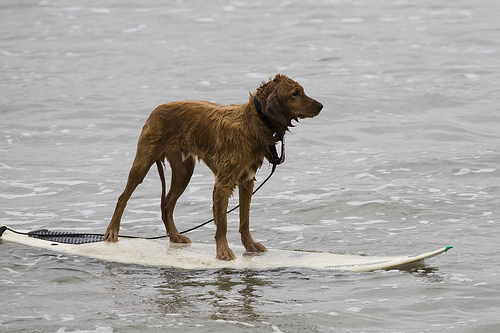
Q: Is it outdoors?
A: Yes, it is outdoors.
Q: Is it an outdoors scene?
A: Yes, it is outdoors.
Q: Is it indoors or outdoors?
A: It is outdoors.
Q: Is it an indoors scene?
A: No, it is outdoors.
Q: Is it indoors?
A: No, it is outdoors.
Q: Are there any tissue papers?
A: No, there are no tissue papers.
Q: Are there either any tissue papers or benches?
A: No, there are no tissue papers or benches.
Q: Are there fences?
A: No, there are no fences.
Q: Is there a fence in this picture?
A: No, there are no fences.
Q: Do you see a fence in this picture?
A: No, there are no fences.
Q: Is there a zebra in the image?
A: No, there are no zebras.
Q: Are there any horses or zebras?
A: No, there are no zebras or horses.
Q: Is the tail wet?
A: Yes, the tail is wet.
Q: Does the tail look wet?
A: Yes, the tail is wet.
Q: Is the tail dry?
A: No, the tail is wet.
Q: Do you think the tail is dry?
A: No, the tail is wet.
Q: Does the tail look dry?
A: No, the tail is wet.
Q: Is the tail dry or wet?
A: The tail is wet.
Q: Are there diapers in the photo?
A: No, there are no diapers.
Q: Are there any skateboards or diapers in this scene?
A: No, there are no diapers or skateboards.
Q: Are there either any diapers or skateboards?
A: No, there are no diapers or skateboards.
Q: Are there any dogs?
A: Yes, there is a dog.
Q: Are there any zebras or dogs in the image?
A: Yes, there is a dog.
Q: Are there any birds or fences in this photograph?
A: No, there are no fences or birds.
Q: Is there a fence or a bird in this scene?
A: No, there are no fences or birds.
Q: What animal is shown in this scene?
A: The animal is a dog.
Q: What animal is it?
A: The animal is a dog.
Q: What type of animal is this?
A: This is a dog.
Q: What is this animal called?
A: This is a dog.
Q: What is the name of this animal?
A: This is a dog.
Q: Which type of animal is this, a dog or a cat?
A: This is a dog.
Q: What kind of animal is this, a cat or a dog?
A: This is a dog.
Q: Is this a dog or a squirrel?
A: This is a dog.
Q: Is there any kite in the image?
A: No, there are no kites.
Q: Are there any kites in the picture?
A: No, there are no kites.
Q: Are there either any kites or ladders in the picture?
A: No, there are no kites or ladders.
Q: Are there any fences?
A: No, there are no fences.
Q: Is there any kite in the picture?
A: No, there are no kites.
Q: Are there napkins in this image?
A: No, there are no napkins.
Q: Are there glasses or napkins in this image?
A: No, there are no napkins or glasses.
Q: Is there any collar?
A: Yes, there is a collar.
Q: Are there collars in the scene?
A: Yes, there is a collar.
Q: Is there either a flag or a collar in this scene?
A: Yes, there is a collar.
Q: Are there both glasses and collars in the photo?
A: No, there is a collar but no glasses.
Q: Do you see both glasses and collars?
A: No, there is a collar but no glasses.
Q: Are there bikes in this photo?
A: No, there are no bikes.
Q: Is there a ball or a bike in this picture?
A: No, there are no bikes or balls.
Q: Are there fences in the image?
A: No, there are no fences.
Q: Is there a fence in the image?
A: No, there are no fences.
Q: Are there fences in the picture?
A: No, there are no fences.